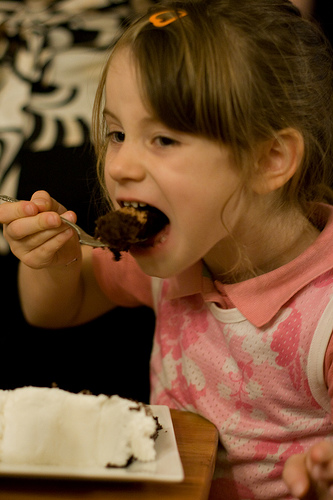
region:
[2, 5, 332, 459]
a little girl eating cake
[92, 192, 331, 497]
her shirt is pink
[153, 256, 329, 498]
her shirt has a pink print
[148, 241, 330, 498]
her shirt has a pink floral print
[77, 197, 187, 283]
a piece of chocolate cake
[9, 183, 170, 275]
piece of cake on a fork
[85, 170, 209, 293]
she is biting the cake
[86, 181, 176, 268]
the cake is in her mouth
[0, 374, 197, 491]
frosting and cake on a white plate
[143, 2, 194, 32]
an orange hair clip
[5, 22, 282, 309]
a young girl is eating a piece of cake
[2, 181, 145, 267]
the girl has a fork in her hand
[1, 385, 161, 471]
a piece of cake is on a plate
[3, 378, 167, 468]
the cake is chocolate with white frosting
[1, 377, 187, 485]
the cake is on a white square plate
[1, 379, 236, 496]
the cake is on a wooden table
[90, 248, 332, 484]
the child is wearing a pink blouse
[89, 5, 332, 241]
the girl has light brown hair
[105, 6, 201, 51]
the girl has an orange barrette in her hair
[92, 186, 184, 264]
the girl has her mouth wide open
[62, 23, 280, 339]
a girl eating cake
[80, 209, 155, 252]
chocolate cake on a spoon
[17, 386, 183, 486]
pastry on a square tray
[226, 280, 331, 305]
a girls peach collar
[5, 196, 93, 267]
a hand gripping cake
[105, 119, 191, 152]
eyes facing right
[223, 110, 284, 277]
hair hanging over neck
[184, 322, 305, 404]
a pink and white flowered shirt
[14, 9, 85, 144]
floral black and white background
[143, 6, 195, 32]
a pink clip in brown hair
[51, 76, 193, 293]
kid is eating a cake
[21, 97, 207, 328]
kid is eating a cake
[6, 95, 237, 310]
kid is eating a cake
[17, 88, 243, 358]
kid is eating a cake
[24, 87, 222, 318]
kid is eating a cake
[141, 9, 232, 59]
the clip is orange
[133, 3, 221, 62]
the clip is orange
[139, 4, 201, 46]
the clip is orange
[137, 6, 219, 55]
the clip is orange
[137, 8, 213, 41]
the clip is orange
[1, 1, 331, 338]
A girl eating cake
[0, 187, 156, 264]
Chocolate cake on a fork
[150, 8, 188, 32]
Orange barrette in girl's hair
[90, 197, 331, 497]
A pink colored shirt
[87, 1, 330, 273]
Brown hair on girl's head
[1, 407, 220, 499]
A brown wooden table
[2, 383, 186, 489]
A white square plate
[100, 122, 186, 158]
A pair of eyes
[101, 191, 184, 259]
A wide open mouth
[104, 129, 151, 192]
Nose on girl's face